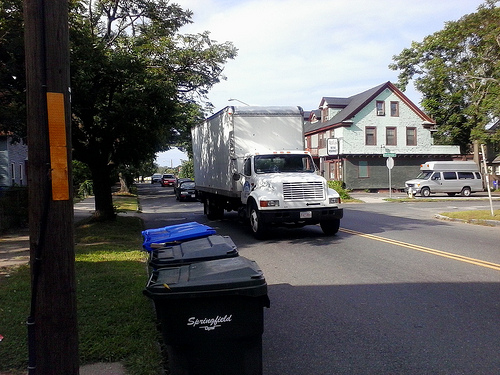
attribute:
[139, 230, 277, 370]
trash cans — black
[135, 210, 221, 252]
trash can — blue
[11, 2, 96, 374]
pole — utility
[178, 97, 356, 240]
truck — closed, white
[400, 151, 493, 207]
van — silver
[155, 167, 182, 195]
mini van — red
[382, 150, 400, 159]
street sign — green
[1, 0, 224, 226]
tree — large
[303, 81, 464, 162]
house — white, gray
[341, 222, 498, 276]
double line — yellow, yelllow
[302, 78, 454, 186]
building — two story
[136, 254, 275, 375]
trash can — black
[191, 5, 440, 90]
sky — blue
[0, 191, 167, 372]
grass — green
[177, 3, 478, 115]
cloud — white